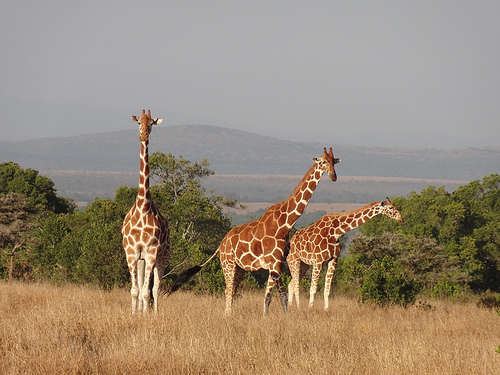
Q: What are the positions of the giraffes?
A: Standing.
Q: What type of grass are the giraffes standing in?
A: Brown.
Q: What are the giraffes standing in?
A: Grass.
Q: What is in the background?
A: Mountain.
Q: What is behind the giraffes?
A: Trees.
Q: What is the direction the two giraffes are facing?
A: Right.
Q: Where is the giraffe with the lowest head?
A: Right.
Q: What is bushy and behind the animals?
A: Shrubs.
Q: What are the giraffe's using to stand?
A: Legs.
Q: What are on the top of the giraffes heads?
A: Horns.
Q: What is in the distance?
A: A mountain.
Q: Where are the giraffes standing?
A: A field.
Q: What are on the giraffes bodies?
A: Spots.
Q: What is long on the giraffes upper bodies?
A: Necks.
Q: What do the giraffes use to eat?
A: Mouths.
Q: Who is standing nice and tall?
A: A giraffe.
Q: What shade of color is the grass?
A: Tan.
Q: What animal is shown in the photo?
A: Giraffe.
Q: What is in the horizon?
A: Mountains.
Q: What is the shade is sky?
A: Gray.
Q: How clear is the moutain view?
A: Cloudy and Hazy.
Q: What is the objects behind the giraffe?
A: Green trees.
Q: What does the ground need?
A: Water.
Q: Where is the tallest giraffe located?
A: On the left.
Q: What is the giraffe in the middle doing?
A: Looking left.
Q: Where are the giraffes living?
A: In the wild.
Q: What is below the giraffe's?
A: Their legs.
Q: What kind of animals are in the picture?
A: Giraffe.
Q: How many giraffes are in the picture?
A: Three.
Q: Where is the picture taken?
A: On the meadow.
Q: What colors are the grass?
A: Yellow.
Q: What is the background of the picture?
A: Forest and mountain.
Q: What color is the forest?
A: Green.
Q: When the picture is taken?
A: In the daytime.